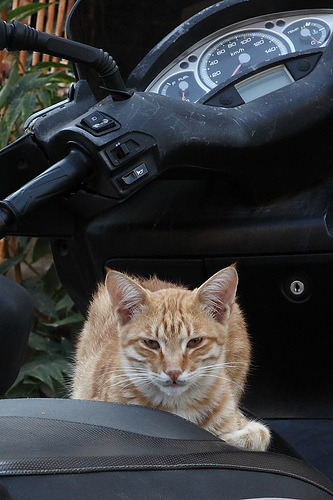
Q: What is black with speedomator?
A: A steering wheel.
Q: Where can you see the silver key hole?
A: Underneath the steering wheel.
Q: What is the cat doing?
A: Sitting on the bike.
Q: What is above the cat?
A: Handle bars.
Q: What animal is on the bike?
A: Orange cat.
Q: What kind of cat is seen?
A: Orange cat.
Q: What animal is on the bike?
A: Cat.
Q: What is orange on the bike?
A: The cat.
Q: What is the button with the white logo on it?
A: Horn.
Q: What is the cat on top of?
A: Black seat.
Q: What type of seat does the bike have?
A: Black seat.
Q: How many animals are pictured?
A: 1.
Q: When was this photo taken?
A: Daytime.